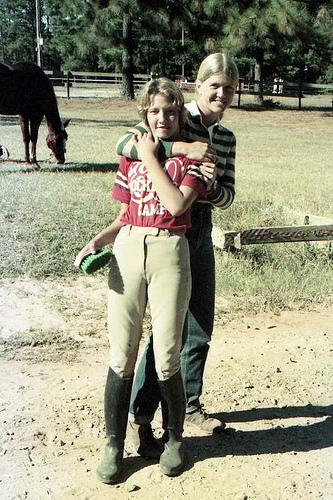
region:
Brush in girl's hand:
[75, 247, 114, 276]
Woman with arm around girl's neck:
[74, 52, 238, 485]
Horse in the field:
[0, 58, 71, 170]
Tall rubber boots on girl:
[95, 366, 187, 483]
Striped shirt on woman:
[116, 99, 238, 208]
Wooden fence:
[36, 64, 331, 105]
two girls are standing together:
[73, 51, 242, 488]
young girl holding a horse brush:
[73, 76, 213, 485]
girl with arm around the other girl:
[118, 50, 241, 460]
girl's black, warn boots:
[95, 366, 192, 486]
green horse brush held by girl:
[71, 245, 113, 274]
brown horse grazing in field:
[0, 56, 74, 173]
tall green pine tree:
[45, 0, 209, 100]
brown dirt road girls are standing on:
[0, 278, 331, 498]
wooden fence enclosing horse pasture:
[231, 73, 332, 110]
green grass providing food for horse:
[0, 82, 332, 305]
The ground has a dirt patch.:
[18, 269, 323, 490]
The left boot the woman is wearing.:
[89, 371, 143, 475]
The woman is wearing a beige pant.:
[96, 222, 196, 379]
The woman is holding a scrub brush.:
[70, 238, 117, 277]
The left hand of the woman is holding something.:
[62, 163, 129, 250]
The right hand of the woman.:
[125, 133, 204, 211]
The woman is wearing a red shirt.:
[110, 152, 194, 225]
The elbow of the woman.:
[154, 191, 199, 216]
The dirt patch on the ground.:
[3, 274, 329, 499]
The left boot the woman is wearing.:
[91, 365, 138, 484]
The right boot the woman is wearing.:
[151, 366, 195, 480]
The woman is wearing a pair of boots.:
[90, 366, 196, 482]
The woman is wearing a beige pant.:
[82, 226, 208, 384]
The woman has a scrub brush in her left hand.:
[74, 246, 125, 281]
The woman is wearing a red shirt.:
[96, 151, 200, 231]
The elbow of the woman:
[151, 188, 196, 222]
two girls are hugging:
[102, 48, 281, 313]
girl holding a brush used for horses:
[64, 228, 129, 286]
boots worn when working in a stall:
[91, 360, 221, 485]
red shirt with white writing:
[114, 147, 220, 240]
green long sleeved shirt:
[187, 103, 238, 206]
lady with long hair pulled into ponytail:
[185, 48, 255, 117]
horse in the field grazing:
[12, 40, 78, 169]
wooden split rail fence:
[242, 68, 303, 118]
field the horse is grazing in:
[56, 85, 107, 214]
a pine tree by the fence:
[63, 6, 144, 100]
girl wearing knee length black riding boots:
[73, 76, 215, 484]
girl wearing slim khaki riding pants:
[74, 76, 213, 381]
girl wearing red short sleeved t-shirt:
[73, 76, 213, 269]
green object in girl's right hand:
[71, 242, 110, 272]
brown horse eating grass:
[0, 54, 77, 168]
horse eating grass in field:
[0, 57, 73, 173]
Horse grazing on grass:
[0, 56, 74, 166]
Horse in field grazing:
[0, 45, 71, 168]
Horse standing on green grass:
[0, 49, 69, 163]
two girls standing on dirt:
[77, 49, 223, 485]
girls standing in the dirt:
[76, 48, 201, 482]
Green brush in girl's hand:
[71, 236, 114, 274]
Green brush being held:
[74, 238, 111, 274]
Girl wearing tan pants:
[94, 73, 187, 484]